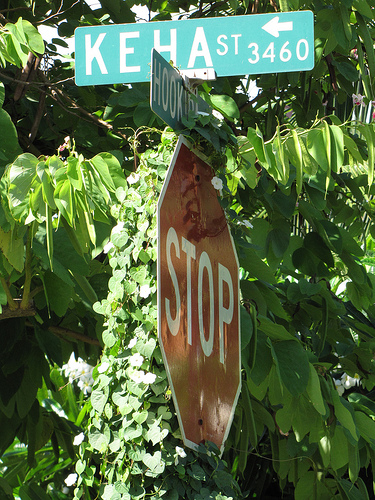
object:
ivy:
[75, 129, 223, 500]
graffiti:
[168, 173, 206, 362]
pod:
[290, 128, 303, 203]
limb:
[226, 112, 361, 168]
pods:
[46, 203, 54, 274]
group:
[4, 142, 128, 319]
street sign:
[73, 7, 315, 86]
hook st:
[153, 57, 184, 125]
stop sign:
[153, 133, 243, 461]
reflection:
[166, 152, 232, 434]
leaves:
[142, 449, 163, 474]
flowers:
[351, 90, 362, 109]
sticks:
[11, 50, 36, 107]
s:
[164, 225, 183, 340]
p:
[216, 260, 237, 369]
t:
[180, 235, 199, 353]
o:
[196, 250, 215, 357]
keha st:
[84, 26, 243, 76]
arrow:
[260, 16, 293, 38]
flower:
[210, 175, 224, 192]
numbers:
[247, 41, 260, 63]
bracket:
[174, 68, 216, 82]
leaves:
[7, 152, 40, 223]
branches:
[28, 68, 53, 146]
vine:
[67, 129, 196, 499]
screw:
[197, 418, 203, 429]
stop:
[165, 222, 236, 368]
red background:
[161, 144, 240, 455]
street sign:
[149, 44, 211, 142]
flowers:
[81, 376, 94, 394]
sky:
[37, 1, 265, 112]